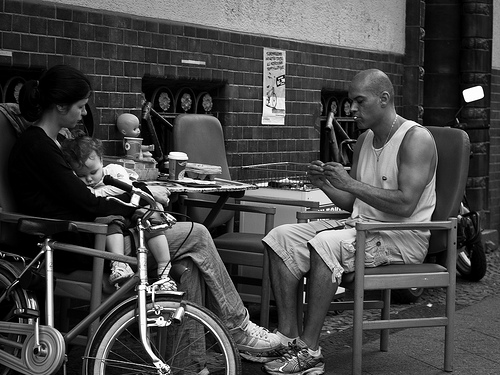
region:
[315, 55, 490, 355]
a man in white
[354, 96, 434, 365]
a man in white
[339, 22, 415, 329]
a man in white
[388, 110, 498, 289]
a man in white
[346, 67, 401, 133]
the head of a man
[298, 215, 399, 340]
the leg of a man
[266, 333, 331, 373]
a tennis shoe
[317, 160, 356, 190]
the hand of a man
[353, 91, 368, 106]
the eye of a man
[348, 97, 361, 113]
the nose of a man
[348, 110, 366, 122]
the mouth of a man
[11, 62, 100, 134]
the head of a woman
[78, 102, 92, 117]
the nose of a woman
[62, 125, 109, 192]
the head of a child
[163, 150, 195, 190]
disposable cup on top of table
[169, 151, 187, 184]
disposable cup on top of table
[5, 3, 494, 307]
the picture is black and white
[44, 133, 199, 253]
the baby is sleeping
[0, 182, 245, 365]
the bike is silver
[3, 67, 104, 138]
the woman has dark hair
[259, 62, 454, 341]
the man is sitting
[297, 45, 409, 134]
the man`s head is bald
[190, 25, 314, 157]
the wall is made of bricks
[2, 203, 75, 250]
the seat is black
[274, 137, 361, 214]
the man is rolling something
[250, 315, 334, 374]
the man is wearing sneakers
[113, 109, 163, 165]
Baby doll sitting on a table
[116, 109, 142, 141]
Baby doll is bald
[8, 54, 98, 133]
The woman has dark hair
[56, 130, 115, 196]
The child has dark hair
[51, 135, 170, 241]
The child is sleeping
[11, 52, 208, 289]
Woman is holding a child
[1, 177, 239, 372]
Bike parked nest to the woman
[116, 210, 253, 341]
The woman is wearing jeans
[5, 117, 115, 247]
The woman is wearing a dark shirt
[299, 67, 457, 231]
Man looks like he's rolling a cigarette